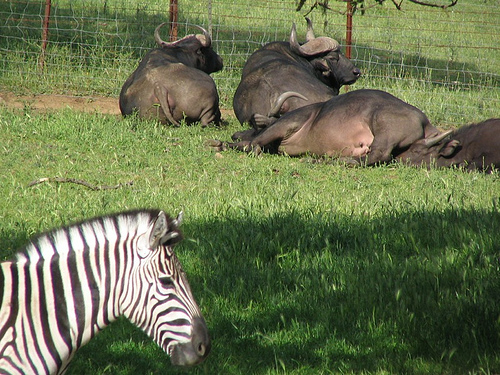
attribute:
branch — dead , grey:
[20, 169, 145, 202]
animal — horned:
[228, 32, 363, 132]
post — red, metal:
[31, 0, 52, 72]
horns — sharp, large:
[152, 21, 212, 46]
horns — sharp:
[153, 17, 213, 48]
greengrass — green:
[2, 0, 499, 372]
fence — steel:
[2, 3, 498, 104]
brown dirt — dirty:
[17, 83, 122, 121]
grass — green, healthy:
[0, 0, 500, 372]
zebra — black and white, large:
[1, 202, 216, 374]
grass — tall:
[228, 178, 498, 337]